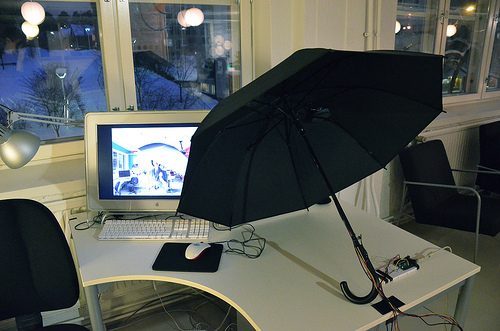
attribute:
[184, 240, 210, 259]
mouse — White apple  